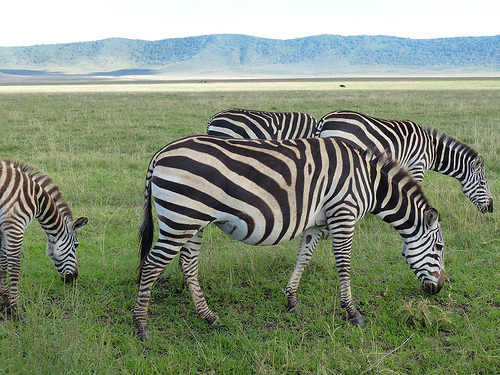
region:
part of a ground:
[243, 306, 272, 347]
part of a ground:
[253, 276, 282, 316]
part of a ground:
[252, 241, 278, 276]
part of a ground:
[262, 261, 285, 288]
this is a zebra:
[166, 139, 448, 316]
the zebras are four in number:
[12, 74, 464, 342]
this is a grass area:
[87, 87, 136, 166]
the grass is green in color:
[274, 320, 336, 364]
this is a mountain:
[206, 32, 303, 65]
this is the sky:
[285, 7, 394, 39]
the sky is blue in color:
[22, 17, 59, 33]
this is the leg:
[330, 211, 364, 326]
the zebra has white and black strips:
[231, 163, 268, 225]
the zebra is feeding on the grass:
[414, 264, 483, 296]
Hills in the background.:
[1, 33, 496, 83]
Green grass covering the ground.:
[1, 93, 498, 374]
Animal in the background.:
[335, 79, 348, 92]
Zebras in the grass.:
[0, 107, 496, 340]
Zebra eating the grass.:
[123, 130, 448, 335]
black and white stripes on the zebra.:
[202, 101, 320, 143]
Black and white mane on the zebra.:
[422, 117, 481, 158]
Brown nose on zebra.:
[421, 263, 446, 293]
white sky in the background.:
[0, 3, 497, 48]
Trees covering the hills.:
[1, 35, 498, 72]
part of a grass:
[261, 314, 296, 359]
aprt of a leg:
[326, 215, 365, 289]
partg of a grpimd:
[251, 300, 277, 351]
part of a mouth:
[425, 267, 439, 298]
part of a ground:
[263, 321, 287, 355]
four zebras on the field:
[15, 84, 478, 372]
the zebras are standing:
[22, 105, 496, 370]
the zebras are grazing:
[19, 98, 493, 344]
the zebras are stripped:
[111, 88, 451, 298]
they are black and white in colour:
[163, 67, 455, 348]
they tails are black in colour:
[128, 193, 150, 259]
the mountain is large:
[46, 24, 498, 86]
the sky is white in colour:
[234, 1, 470, 33]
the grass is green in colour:
[56, 98, 129, 160]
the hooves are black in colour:
[342, 308, 370, 329]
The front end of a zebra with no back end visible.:
[0, 152, 87, 317]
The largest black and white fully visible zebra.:
[130, 135, 441, 340]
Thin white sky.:
[0, 0, 496, 36]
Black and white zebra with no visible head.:
[201, 107, 316, 137]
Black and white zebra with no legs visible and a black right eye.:
[315, 107, 491, 209]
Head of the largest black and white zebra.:
[403, 205, 443, 295]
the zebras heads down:
[0, 100, 495, 345]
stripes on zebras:
[0, 100, 491, 340]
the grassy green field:
[0, 86, 495, 366]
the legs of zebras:
[0, 217, 365, 343]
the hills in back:
[0, 28, 498, 68]